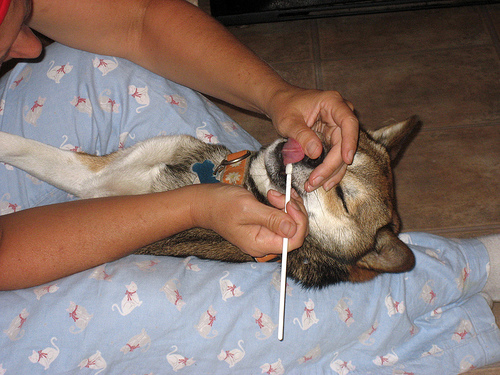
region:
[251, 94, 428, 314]
A dog heads.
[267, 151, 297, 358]
A woman trying to clean a dogs teeth.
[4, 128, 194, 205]
The bottom half of a dog.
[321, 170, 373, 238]
the left eye of a dog.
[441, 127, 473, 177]
The floor near a woman laying down.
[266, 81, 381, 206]
The left hand of a woman.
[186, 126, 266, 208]
A dog tag on a dog's neck.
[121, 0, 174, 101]
A crease in a woman's left arm.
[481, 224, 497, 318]
A sock covered section of a leg.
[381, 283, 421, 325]
White print on a woman's outfit.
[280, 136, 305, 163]
dog has tongue out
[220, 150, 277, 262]
dog wearing orange collar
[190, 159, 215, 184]
dog has blue tag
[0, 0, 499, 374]
person holding dog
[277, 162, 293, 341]
person holding long white q-tip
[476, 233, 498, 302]
person wearing white sock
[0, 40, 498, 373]
person wearing blue pajama pants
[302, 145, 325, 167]
dog has black nose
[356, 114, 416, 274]
dog has two ears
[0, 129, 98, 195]
dog has white leg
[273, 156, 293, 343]
White toothbrush in a dog's mouth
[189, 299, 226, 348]
White cat design on light blue pajamas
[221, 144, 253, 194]
Dog's orange collar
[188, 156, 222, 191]
Dog's blue bone tag on a collar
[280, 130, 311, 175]
Dog's red tongue licking a toothbrush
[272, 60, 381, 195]
Left hand of a person holding a dog's head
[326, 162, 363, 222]
Dog's closed left eye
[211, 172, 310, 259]
Person's right hand holding a white stick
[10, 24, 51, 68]
Top of a person's nose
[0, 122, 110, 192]
Dog's right front paw in the middle of someone's legs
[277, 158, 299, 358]
white q-tip to clean dog's teeth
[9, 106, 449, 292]
dog in a female's lap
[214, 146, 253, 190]
orange collar on dog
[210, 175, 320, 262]
right hand with a q-tip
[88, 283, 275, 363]
blue pajama pants of female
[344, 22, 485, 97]
brown flooring where female is sitting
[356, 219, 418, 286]
left ear of a dog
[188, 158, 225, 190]
blue bone identification tag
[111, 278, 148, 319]
white cat design on pajama pants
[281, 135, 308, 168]
pink tongue of a dog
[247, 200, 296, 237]
the finger of person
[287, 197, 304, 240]
the finger of person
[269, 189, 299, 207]
the finger of person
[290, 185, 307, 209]
the finger of person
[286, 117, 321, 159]
the finger of person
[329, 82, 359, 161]
the finger of person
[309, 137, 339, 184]
the finger of person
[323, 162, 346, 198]
the finger of person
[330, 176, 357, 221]
the eye of a cat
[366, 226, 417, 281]
the ear of a cat